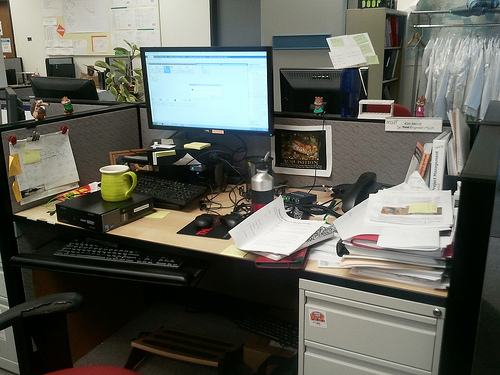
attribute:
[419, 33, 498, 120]
smocks — white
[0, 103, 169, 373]
cubicle dividers — black, gray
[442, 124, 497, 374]
cubicle dividers — black, gray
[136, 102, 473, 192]
cubicle dividers — black, gray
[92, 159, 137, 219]
mug — green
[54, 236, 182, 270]
keyboard — black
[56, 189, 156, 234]
cpu — black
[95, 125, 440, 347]
desk — low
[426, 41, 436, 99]
top — white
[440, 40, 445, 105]
top — white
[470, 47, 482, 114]
top — white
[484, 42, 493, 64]
top — white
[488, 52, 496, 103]
top — white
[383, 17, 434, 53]
hanger — wooden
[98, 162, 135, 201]
cup — lime green, ceramic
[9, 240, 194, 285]
keyboard — black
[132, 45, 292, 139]
monitor — black framed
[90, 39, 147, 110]
plant — green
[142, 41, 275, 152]
monitor — flat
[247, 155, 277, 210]
bottle — silver, black, red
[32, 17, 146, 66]
wall — white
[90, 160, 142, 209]
coffee mug — green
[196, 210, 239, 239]
mouse — black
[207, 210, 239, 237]
mouse — black